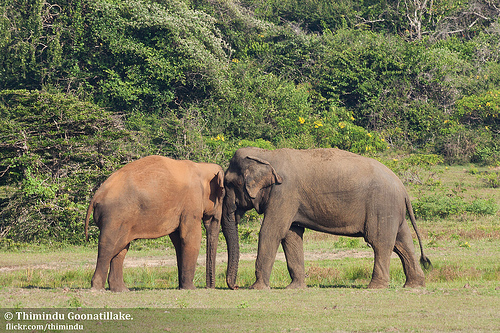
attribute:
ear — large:
[213, 170, 223, 200]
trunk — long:
[205, 215, 217, 289]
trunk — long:
[219, 215, 238, 289]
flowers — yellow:
[279, 102, 392, 154]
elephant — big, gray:
[235, 149, 456, 317]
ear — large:
[238, 152, 280, 199]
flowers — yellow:
[291, 109, 379, 139]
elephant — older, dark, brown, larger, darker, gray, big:
[219, 138, 432, 295]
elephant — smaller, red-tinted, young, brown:
[84, 154, 224, 291]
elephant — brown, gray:
[106, 114, 411, 316]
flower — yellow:
[315, 117, 323, 129]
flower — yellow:
[296, 114, 305, 124]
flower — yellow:
[337, 120, 344, 129]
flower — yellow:
[364, 143, 372, 149]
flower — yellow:
[334, 120, 346, 126]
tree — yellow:
[195, 51, 376, 152]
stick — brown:
[42, 114, 163, 157]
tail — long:
[405, 187, 435, 271]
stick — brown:
[61, 164, 109, 176]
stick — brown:
[17, 125, 31, 152]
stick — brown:
[50, 118, 62, 130]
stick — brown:
[85, 104, 125, 135]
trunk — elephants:
[223, 188, 241, 287]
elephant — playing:
[30, 121, 258, 284]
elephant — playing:
[195, 124, 459, 307]